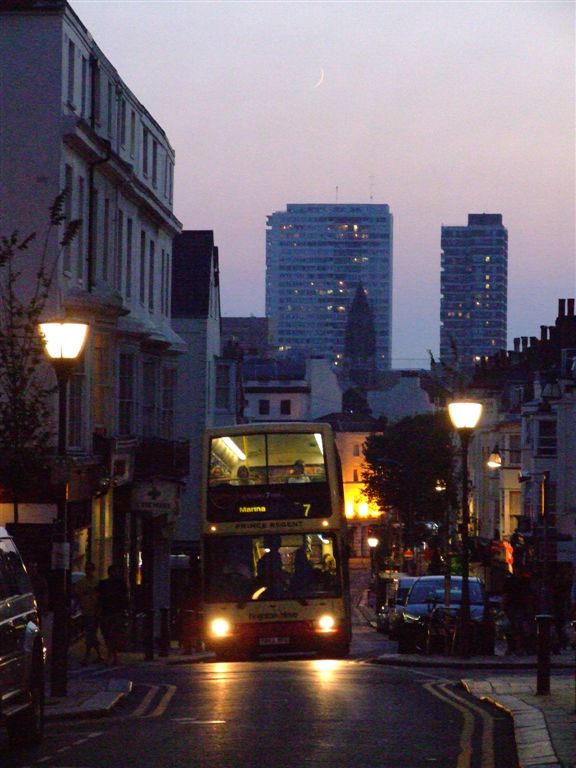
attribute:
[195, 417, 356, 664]
bus — number 7, double decker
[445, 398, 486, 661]
street lamp — yellow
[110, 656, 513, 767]
street — busy, black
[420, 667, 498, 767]
lines — yellow